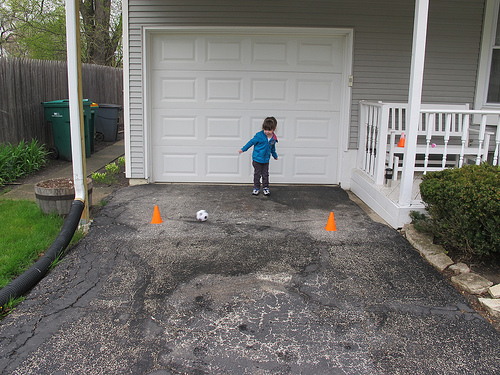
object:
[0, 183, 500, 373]
ground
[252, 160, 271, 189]
pants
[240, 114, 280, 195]
child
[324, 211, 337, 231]
cone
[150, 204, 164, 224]
cone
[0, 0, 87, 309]
drive way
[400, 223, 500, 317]
stones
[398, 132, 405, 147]
cone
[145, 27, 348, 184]
garage door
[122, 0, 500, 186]
garage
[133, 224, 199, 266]
gray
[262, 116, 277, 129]
hair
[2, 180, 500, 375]
driveway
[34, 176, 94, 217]
planter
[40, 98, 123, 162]
bin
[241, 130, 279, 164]
jacket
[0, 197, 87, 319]
grass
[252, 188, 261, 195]
shoe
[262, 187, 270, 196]
shoe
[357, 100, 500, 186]
handrail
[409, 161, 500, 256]
bush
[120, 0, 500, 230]
house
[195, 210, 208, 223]
ball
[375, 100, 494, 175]
bench